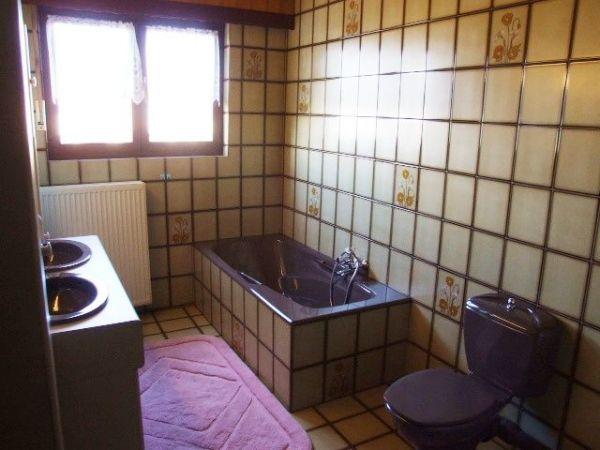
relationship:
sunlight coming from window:
[48, 20, 218, 144] [36, 6, 218, 158]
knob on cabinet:
[28, 74, 37, 90] [14, 0, 35, 125]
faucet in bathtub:
[332, 250, 364, 280] [192, 233, 412, 414]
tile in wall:
[350, 192, 369, 237] [284, 3, 599, 446]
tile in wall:
[474, 229, 516, 284] [282, 9, 595, 334]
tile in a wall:
[474, 122, 520, 183] [320, 26, 596, 367]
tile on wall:
[448, 115, 482, 176] [303, 26, 581, 327]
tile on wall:
[555, 124, 597, 205] [291, 10, 585, 378]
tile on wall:
[530, 7, 571, 59] [291, 10, 585, 378]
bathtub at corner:
[192, 231, 412, 412] [191, 3, 411, 440]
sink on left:
[40, 232, 141, 383] [5, 2, 242, 447]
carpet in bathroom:
[137, 333, 313, 448] [5, 3, 596, 448]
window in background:
[47, 14, 219, 143] [23, 3, 289, 307]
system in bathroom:
[383, 292, 566, 450] [5, 3, 596, 448]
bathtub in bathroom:
[192, 233, 412, 414] [5, 3, 596, 448]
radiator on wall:
[36, 182, 154, 306] [27, 2, 286, 309]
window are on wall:
[41, 14, 218, 156] [27, 2, 286, 309]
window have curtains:
[41, 14, 218, 156] [44, 12, 222, 104]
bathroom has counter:
[5, 3, 596, 448] [40, 233, 143, 447]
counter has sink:
[40, 233, 143, 447] [40, 239, 92, 271]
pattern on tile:
[397, 169, 415, 208] [392, 162, 420, 211]